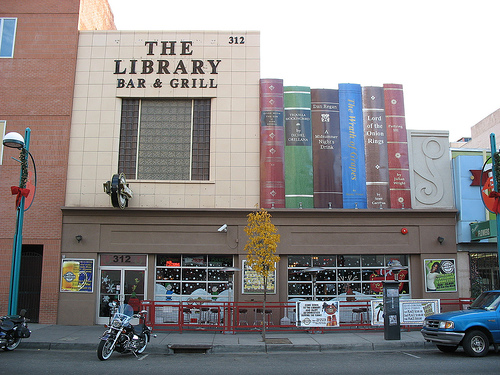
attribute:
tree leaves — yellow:
[238, 206, 287, 345]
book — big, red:
[256, 75, 286, 210]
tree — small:
[243, 206, 279, 348]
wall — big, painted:
[148, 258, 235, 338]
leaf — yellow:
[271, 252, 281, 262]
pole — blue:
[1, 126, 41, 315]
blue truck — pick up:
[420, 291, 498, 358]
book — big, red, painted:
[384, 84, 416, 210]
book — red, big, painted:
[347, 75, 398, 210]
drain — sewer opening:
[168, 342, 212, 354]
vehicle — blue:
[418, 286, 499, 373]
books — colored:
[256, 64, 437, 228]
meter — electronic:
[370, 272, 407, 351]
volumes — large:
[259, 77, 412, 209]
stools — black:
[167, 296, 384, 334]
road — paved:
[7, 349, 498, 366]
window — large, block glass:
[117, 96, 219, 179]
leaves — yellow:
[236, 214, 288, 267]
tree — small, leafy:
[230, 203, 295, 350]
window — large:
[118, 97, 212, 182]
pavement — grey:
[0, 344, 496, 374]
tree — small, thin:
[242, 205, 281, 342]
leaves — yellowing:
[243, 207, 281, 278]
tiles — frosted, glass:
[134, 99, 192, 177]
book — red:
[382, 81, 413, 208]